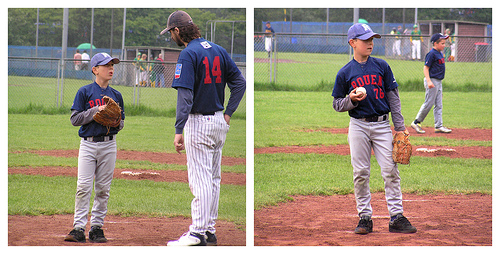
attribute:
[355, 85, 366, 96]
baseball — white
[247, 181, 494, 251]
sand — red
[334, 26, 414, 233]
pitcher — young, savvy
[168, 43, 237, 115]
shirt — blue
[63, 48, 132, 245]
pitcher — young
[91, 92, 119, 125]
glove — brown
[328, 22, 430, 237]
pitcher — young, blue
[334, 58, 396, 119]
jersey — dark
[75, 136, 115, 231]
baseball pants — gray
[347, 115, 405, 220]
baseball pants — gray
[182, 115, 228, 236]
baseball pants — gray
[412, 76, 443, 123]
baseball pants — gray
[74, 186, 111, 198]
knees — dirty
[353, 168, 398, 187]
knees — dirty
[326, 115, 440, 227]
pants — gray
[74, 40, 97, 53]
umbrella — green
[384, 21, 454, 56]
pitchers — other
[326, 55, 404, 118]
shirts — blue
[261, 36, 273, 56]
pants — white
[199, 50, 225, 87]
number — 14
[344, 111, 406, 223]
pitcher — young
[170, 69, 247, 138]
shirt — long sleeved